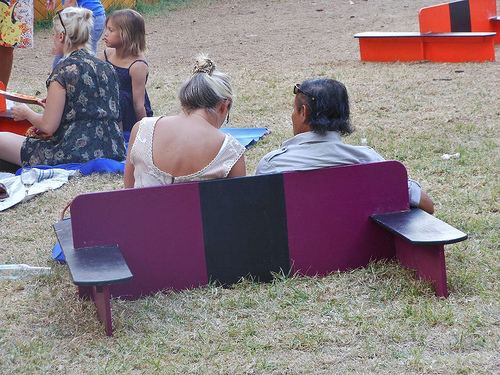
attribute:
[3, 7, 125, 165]
person — sitting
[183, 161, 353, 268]
seat — wooden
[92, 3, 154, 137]
girl — little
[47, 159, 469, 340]
seat — black, purple